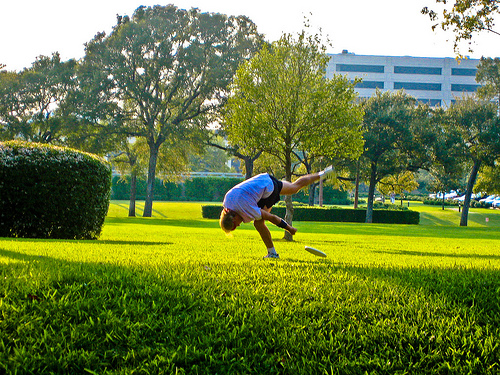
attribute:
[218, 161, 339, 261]
man — bent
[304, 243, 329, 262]
frisbee — white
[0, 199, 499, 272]
grass — short, green, the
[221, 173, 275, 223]
shirt — white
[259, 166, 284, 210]
shorts — black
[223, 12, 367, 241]
tree — canopy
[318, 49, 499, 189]
building — tall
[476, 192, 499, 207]
car — parked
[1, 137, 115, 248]
shrub — nicely cutted, huge, green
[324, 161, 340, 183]
sneaker — raised, white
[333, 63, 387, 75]
window — long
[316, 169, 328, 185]
sock — white